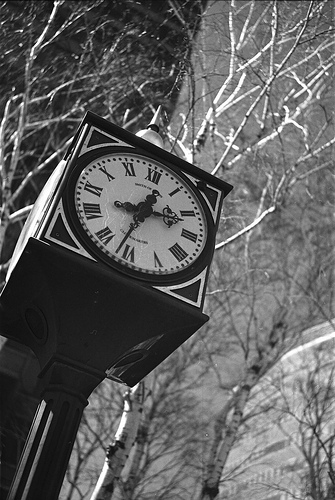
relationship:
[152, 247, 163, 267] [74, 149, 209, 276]
number on clock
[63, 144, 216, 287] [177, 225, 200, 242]
clock has numeral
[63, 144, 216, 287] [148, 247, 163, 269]
clock has numeral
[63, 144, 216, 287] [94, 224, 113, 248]
clock has roman number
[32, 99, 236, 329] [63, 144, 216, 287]
box face has clock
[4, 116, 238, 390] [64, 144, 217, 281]
box has clock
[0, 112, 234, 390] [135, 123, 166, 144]
box has globe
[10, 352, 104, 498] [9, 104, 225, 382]
pole holding clock face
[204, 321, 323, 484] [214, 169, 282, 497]
building behind tree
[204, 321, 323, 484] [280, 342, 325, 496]
building behind tree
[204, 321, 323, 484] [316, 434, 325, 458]
building behind tree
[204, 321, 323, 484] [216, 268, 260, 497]
building behind tree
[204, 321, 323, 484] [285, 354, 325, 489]
building behind tree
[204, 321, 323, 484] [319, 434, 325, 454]
building behind tree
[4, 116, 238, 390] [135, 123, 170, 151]
box has globe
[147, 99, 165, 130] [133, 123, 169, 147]
cone on top of globe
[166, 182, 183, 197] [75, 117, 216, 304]
number on clock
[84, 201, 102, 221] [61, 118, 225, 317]
number on clock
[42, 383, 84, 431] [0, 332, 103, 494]
shadow on pole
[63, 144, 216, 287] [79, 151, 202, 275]
clock shows 2:32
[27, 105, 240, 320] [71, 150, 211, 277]
clock shows 2:32